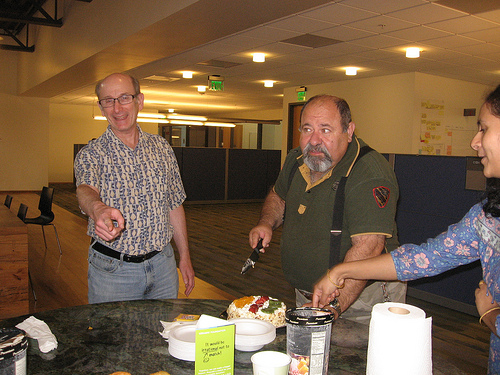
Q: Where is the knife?
A: Guys hand.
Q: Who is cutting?
A: The guy.